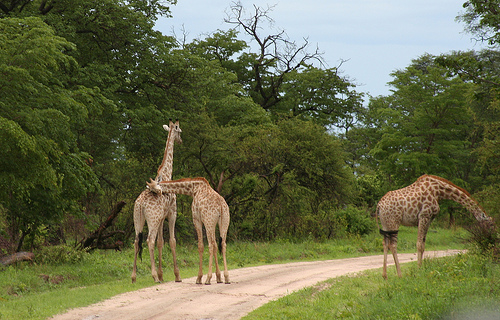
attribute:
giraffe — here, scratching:
[145, 177, 231, 286]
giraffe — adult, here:
[129, 122, 184, 286]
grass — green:
[1, 228, 384, 317]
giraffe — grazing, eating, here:
[376, 174, 500, 279]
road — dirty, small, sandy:
[49, 247, 472, 320]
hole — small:
[438, 293, 498, 319]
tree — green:
[1, 202, 126, 269]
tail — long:
[136, 199, 147, 263]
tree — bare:
[200, 0, 347, 118]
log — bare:
[79, 200, 128, 249]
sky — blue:
[152, 1, 497, 107]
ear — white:
[163, 125, 170, 131]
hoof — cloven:
[205, 279, 211, 286]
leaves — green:
[14, 29, 94, 182]